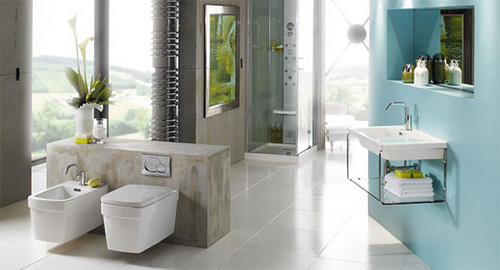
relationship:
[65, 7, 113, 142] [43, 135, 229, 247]
plant on island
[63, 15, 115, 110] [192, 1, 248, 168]
plant on wall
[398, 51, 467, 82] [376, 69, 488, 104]
toiletries are on shelf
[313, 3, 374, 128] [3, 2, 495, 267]
window in bathroom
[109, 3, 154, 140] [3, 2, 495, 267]
window in bathroom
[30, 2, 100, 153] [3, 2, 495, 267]
window in bathroom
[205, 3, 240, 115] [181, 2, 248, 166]
picture hanging on wall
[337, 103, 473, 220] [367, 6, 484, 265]
sink on wall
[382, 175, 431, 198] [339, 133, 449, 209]
towel on shelf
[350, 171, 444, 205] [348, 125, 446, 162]
shelf under sink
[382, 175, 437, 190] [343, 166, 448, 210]
towel on shelf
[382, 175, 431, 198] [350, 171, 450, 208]
towel on shelf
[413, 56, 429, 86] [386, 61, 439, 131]
bottle of lotion